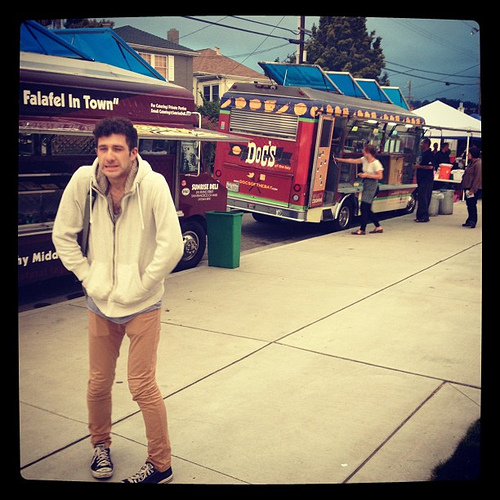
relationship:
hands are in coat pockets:
[83, 273, 146, 304] [80, 261, 158, 312]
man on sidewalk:
[47, 115, 188, 483] [19, 191, 490, 480]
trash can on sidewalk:
[207, 207, 242, 272] [19, 191, 490, 480]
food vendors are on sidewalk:
[15, 26, 481, 295] [19, 191, 490, 480]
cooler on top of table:
[434, 158, 453, 181] [421, 168, 477, 205]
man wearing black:
[410, 134, 438, 224] [411, 136, 438, 225]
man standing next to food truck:
[410, 134, 438, 224] [208, 61, 435, 236]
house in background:
[108, 20, 195, 92] [20, 13, 477, 117]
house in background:
[182, 42, 282, 100] [20, 13, 477, 117]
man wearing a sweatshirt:
[47, 115, 188, 483] [51, 154, 186, 315]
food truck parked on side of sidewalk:
[208, 61, 435, 236] [19, 191, 490, 480]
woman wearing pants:
[456, 143, 482, 230] [463, 186, 481, 227]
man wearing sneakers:
[47, 115, 188, 483] [84, 443, 180, 484]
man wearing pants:
[47, 115, 188, 483] [79, 307, 181, 475]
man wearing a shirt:
[410, 134, 438, 224] [415, 148, 438, 186]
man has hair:
[47, 115, 188, 483] [90, 118, 142, 149]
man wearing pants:
[410, 134, 438, 224] [412, 176, 438, 223]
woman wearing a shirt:
[336, 143, 389, 236] [359, 156, 384, 177]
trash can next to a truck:
[207, 207, 242, 272] [19, 44, 232, 297]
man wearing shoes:
[47, 115, 188, 483] [84, 443, 180, 484]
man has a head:
[47, 115, 188, 483] [87, 115, 144, 178]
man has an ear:
[47, 115, 188, 483] [130, 146, 140, 164]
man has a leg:
[47, 115, 188, 483] [123, 331, 177, 472]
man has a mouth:
[47, 115, 188, 483] [102, 162, 127, 174]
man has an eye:
[47, 115, 188, 483] [112, 145, 128, 155]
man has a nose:
[47, 115, 188, 483] [105, 151, 114, 165]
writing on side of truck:
[22, 86, 126, 116] [19, 44, 232, 297]